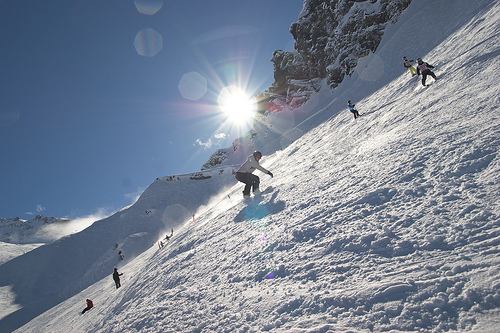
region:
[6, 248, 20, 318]
Red and white stop sign in the sky.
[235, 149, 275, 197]
this is a person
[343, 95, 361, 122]
this is a person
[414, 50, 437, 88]
this is a person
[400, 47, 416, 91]
this is a person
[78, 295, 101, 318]
this is a person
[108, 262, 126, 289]
this is a person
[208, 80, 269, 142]
these are suns rays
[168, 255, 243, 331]
this is an icy slope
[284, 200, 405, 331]
this is an icy slope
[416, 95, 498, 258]
this is an icy slope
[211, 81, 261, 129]
A bright reflection of light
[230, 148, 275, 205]
A snowboarder going downhill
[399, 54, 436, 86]
Two snowboarders on a hill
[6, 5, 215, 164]
A blue sky without clouds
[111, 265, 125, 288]
Man standing on a snowy hill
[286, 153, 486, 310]
Tracks through snowy side of a mountain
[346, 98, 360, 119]
A skier on the snowy hill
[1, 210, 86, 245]
Mountain range in the distance.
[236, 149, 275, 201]
A man on his board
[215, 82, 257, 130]
A bright reflection of the sunlight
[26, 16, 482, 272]
these people are skiing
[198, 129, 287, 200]
the man is is in motion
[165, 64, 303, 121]
the sun is very bright here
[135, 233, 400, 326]
the sun is reflection on the snow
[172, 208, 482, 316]
the snow is rough here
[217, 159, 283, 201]
the man has black pants on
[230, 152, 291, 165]
the man has a white jacket on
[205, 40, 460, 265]
people in the snow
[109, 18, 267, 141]
reflection of the sun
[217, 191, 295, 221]
shadow of the man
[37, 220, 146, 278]
shadow on the hill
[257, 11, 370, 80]
snow on the hill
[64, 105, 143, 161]
the sky is clear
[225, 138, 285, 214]
the man is snowboarding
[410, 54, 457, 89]
the people are snowboarding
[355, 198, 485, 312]
tracks in the snow